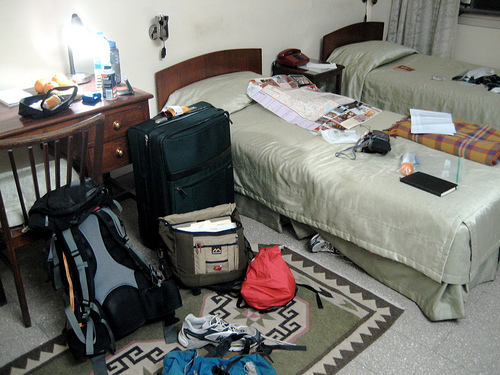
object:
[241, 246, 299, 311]
bag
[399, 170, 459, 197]
book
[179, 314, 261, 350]
sneaker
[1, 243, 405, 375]
rug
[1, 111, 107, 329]
chair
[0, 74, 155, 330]
desk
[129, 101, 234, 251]
luggage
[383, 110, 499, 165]
blanket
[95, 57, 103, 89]
bottle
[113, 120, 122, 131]
knob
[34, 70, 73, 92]
oranges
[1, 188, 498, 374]
ground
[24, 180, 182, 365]
hiking pack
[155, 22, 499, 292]
bed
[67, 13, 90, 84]
lamp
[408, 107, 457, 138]
papers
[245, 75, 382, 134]
map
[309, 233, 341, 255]
sneaker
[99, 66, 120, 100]
shaving cream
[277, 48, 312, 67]
phone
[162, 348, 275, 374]
backpack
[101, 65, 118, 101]
bottles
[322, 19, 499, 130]
bed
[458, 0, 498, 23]
window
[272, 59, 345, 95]
nightstand